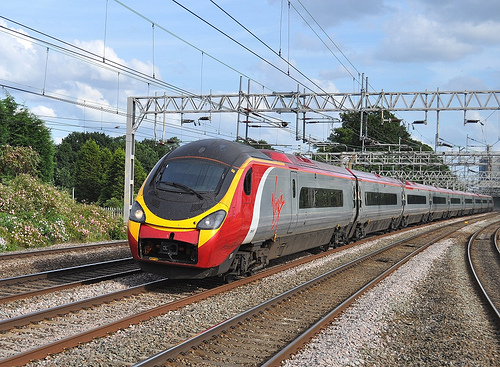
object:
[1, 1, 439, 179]
wires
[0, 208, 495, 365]
gravel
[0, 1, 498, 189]
sky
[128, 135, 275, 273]
front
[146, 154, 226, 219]
windshield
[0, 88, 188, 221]
trees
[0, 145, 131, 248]
flowers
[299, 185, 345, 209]
window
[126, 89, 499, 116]
beam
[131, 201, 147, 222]
headlight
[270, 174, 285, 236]
writing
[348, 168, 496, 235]
cars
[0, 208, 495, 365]
set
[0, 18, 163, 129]
cloud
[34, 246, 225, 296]
shadow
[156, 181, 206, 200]
wiper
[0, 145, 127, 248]
bushes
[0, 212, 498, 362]
rails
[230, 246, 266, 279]
wheels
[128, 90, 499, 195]
metal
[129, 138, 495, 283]
train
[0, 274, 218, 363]
tracks